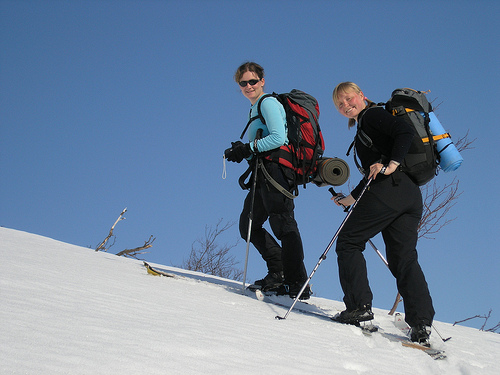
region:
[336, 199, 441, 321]
the pants are black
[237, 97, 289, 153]
the shirt is blue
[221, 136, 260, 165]
the gloves are black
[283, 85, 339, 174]
the backpak is red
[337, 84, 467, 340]
the woman is climbing the slope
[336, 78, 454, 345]
the woman is smiling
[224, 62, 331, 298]
the sunglasses are black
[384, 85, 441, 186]
the bag is black and grey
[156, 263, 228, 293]
shadow is on the ground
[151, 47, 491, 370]
a man is skiing in the snow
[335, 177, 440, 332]
the pants are black in color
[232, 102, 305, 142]
the sweater is lightblue in coor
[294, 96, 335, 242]
the bag is red in color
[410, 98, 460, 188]
the roll is blue in color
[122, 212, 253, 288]
the branches are driied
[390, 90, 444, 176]
this is a bag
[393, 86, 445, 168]
the bag is heavy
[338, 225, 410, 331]
these are the legs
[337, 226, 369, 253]
this is the knee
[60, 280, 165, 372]
the snow is white in colorr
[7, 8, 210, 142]
these are the sky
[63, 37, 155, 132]
the sky is clear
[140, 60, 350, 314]
A woman skiing up a hill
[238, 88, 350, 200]
A red and black back pack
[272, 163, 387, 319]
A silver ski pole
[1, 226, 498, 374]
A snow covered ground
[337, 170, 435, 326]
A pair of black ski pants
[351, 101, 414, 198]
A black long sleeved shirt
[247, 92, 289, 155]
A blue long sleeved shirt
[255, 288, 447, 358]
A pair of white skis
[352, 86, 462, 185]
A black back pack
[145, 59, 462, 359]
two hikers in the snow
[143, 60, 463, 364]
two women hiking up the kill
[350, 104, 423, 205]
black shirt on the woman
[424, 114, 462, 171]
blue yoga mat on the backpack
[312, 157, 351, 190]
black yoga mat on the backpack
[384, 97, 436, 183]
black and gray backpack on the woman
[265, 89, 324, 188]
red and black backpack on the woman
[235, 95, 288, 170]
blue shirt on the woman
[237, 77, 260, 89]
black sunglasses on the woman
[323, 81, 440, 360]
woman with blonde hair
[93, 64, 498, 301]
a couple of girls smiling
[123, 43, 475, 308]
some skiers going uphill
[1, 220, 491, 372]
snow on the ground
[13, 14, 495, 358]
a scene outside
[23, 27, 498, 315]
a scene during the day time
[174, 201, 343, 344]
a tree in the background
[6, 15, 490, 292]
a blue sky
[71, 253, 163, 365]
snow covering the ground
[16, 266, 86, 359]
white snow covering the ground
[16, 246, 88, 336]
ground covered in white snow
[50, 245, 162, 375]
ground covered in snow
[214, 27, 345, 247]
a woman wearing sunglasses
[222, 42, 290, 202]
a woman wearing a shirt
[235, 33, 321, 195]
a woman wearing a blue shirt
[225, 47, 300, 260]
a woma nwearing pants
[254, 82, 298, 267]
a woman wearing black pants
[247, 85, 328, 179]
backpack is red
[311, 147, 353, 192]
bed roll attached to backpack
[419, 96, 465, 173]
bed mat is blue